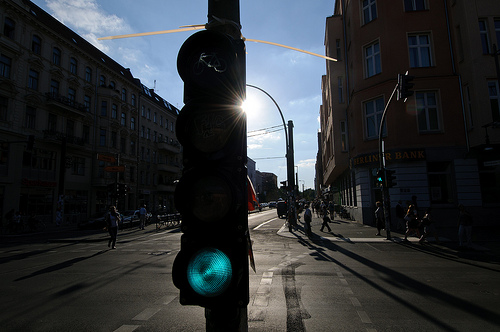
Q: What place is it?
A: It is a road.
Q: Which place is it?
A: It is a road.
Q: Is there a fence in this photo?
A: No, there are no fences.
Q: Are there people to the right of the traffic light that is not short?
A: Yes, there is a person to the right of the traffic light.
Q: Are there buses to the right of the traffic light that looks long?
A: No, there is a person to the right of the signal light.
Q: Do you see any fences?
A: No, there are no fences.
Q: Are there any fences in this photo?
A: No, there are no fences.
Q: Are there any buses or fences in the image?
A: No, there are no fences or buses.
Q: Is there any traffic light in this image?
A: Yes, there is a traffic light.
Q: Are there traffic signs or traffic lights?
A: Yes, there is a traffic light.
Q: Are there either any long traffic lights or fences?
A: Yes, there is a long traffic light.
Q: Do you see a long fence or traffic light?
A: Yes, there is a long traffic light.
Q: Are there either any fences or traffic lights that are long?
A: Yes, the traffic light is long.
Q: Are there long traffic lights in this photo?
A: Yes, there is a long traffic light.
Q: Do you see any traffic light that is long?
A: Yes, there is a traffic light that is long.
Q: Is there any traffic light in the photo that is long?
A: Yes, there is a traffic light that is long.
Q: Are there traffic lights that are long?
A: Yes, there is a traffic light that is long.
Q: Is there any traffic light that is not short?
A: Yes, there is a long traffic light.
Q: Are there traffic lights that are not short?
A: Yes, there is a long traffic light.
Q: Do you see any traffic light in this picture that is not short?
A: Yes, there is a long traffic light.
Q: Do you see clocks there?
A: No, there are no clocks.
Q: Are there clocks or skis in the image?
A: No, there are no clocks or skis.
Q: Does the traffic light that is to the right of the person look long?
A: Yes, the signal light is long.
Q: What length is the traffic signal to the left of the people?
A: The signal light is long.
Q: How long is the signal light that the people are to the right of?
A: The signal light is long.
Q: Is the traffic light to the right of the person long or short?
A: The traffic signal is long.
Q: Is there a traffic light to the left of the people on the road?
A: Yes, there is a traffic light to the left of the people.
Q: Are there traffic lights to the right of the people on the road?
A: No, the traffic light is to the left of the people.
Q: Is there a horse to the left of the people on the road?
A: No, there is a traffic light to the left of the people.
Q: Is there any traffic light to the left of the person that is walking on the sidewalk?
A: Yes, there is a traffic light to the left of the person.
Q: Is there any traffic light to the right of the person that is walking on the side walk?
A: No, the traffic light is to the left of the person.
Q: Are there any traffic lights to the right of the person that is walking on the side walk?
A: No, the traffic light is to the left of the person.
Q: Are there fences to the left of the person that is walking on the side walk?
A: No, there is a traffic light to the left of the person.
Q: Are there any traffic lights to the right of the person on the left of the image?
A: Yes, there is a traffic light to the right of the person.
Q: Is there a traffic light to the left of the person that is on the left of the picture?
A: No, the traffic light is to the right of the person.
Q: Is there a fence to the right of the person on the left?
A: No, there is a traffic light to the right of the person.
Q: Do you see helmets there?
A: No, there are no helmets.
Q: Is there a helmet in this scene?
A: No, there are no helmets.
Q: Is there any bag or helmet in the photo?
A: No, there are no helmets or bags.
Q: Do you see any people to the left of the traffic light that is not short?
A: Yes, there is a person to the left of the traffic signal.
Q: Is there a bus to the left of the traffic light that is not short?
A: No, there is a person to the left of the traffic light.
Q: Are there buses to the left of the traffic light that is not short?
A: No, there is a person to the left of the traffic light.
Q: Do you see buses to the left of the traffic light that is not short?
A: No, there is a person to the left of the traffic light.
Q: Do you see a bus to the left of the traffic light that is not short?
A: No, there is a person to the left of the traffic light.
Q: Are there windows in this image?
A: Yes, there is a window.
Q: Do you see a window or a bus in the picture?
A: Yes, there is a window.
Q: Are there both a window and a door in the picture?
A: No, there is a window but no doors.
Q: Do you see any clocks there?
A: No, there are no clocks.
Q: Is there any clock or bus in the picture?
A: No, there are no clocks or buses.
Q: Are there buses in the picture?
A: No, there are no buses.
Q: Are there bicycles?
A: No, there are no bicycles.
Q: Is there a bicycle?
A: No, there are no bicycles.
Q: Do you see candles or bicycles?
A: No, there are no bicycles or candles.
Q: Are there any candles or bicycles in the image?
A: No, there are no bicycles or candles.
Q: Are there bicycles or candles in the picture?
A: No, there are no bicycles or candles.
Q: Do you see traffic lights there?
A: Yes, there is a traffic light.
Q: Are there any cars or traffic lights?
A: Yes, there is a traffic light.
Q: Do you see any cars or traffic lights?
A: Yes, there is a traffic light.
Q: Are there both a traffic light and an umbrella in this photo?
A: No, there is a traffic light but no umbrellas.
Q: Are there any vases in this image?
A: No, there are no vases.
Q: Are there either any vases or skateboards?
A: No, there are no vases or skateboards.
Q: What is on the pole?
A: The traffic signal is on the pole.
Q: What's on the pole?
A: The traffic signal is on the pole.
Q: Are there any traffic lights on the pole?
A: Yes, there is a traffic light on the pole.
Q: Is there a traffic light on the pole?
A: Yes, there is a traffic light on the pole.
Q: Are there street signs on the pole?
A: No, there is a traffic light on the pole.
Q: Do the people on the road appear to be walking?
A: Yes, the people are walking.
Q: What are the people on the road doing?
A: The people are walking.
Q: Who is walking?
A: The people are walking.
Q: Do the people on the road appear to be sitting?
A: No, the people are walking.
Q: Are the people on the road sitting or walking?
A: The people are walking.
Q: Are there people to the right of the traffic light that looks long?
A: Yes, there are people to the right of the traffic light.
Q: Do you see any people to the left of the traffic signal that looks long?
A: No, the people are to the right of the traffic signal.